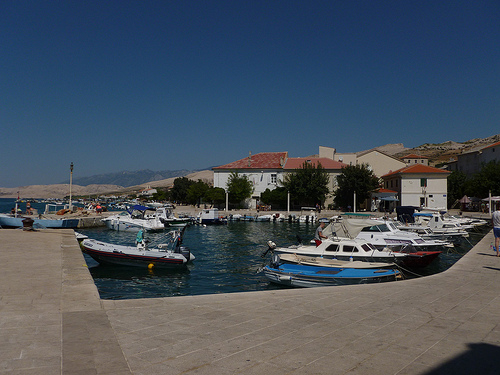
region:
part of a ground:
[177, 300, 227, 356]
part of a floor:
[318, 299, 343, 354]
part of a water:
[210, 258, 233, 287]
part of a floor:
[273, 295, 296, 330]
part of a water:
[201, 223, 223, 258]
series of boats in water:
[263, 204, 438, 275]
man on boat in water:
[308, 213, 331, 246]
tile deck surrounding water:
[107, 283, 456, 366]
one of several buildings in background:
[393, 158, 455, 210]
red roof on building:
[216, 148, 288, 170]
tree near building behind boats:
[292, 160, 334, 207]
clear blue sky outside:
[7, 5, 497, 130]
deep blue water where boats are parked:
[190, 225, 258, 288]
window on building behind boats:
[417, 175, 433, 190]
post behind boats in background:
[62, 157, 77, 211]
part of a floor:
[243, 303, 273, 363]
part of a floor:
[253, 288, 283, 334]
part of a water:
[228, 230, 264, 279]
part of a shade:
[462, 321, 492, 368]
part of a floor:
[261, 322, 292, 367]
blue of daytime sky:
[5, 2, 496, 193]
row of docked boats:
[263, 208, 485, 284]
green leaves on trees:
[170, 162, 378, 208]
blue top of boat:
[263, 265, 398, 281]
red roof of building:
[218, 149, 342, 178]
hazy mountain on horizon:
[55, 165, 197, 190]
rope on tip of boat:
[389, 260, 420, 279]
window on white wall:
[259, 170, 282, 188]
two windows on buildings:
[404, 173, 446, 210]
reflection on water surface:
[88, 260, 183, 296]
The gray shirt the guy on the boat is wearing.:
[315, 220, 327, 240]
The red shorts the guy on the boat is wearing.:
[314, 240, 321, 247]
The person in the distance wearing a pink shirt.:
[94, 202, 102, 207]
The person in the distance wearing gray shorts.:
[93, 206, 105, 212]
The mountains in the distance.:
[75, 163, 186, 181]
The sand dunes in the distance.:
[2, 178, 165, 190]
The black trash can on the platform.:
[15, 210, 40, 233]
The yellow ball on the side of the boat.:
[136, 260, 158, 271]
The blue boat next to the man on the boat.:
[269, 253, 392, 283]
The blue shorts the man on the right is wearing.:
[492, 223, 498, 234]